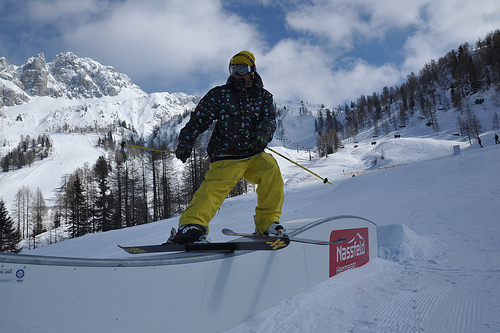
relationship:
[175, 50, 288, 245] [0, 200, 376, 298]
man on ski slide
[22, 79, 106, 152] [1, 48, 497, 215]
snow covers mountain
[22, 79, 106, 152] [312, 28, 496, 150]
snow covers trees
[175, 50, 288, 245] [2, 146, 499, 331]
man on rail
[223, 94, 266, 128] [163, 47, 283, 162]
design on jacket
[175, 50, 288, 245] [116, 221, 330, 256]
man on skis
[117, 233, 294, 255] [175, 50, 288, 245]
ski uner man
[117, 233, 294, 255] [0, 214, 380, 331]
ski over railing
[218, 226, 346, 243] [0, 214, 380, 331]
ski over railing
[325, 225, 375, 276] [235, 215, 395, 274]
logo on railing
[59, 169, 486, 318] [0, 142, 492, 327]
snow on hill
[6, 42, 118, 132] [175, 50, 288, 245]
hill behind man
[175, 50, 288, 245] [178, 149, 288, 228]
man wears pants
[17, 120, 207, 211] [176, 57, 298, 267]
trees behind skier